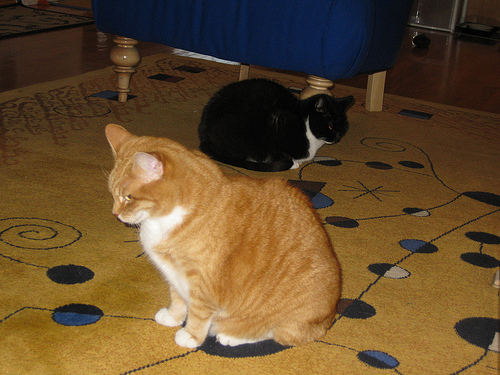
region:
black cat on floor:
[171, 68, 362, 192]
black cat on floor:
[197, 47, 355, 288]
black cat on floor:
[220, 42, 431, 153]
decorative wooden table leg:
[106, 33, 141, 103]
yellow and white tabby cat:
[96, 118, 353, 352]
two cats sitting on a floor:
[107, 62, 363, 356]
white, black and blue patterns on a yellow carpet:
[357, 128, 493, 348]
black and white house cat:
[194, 67, 358, 177]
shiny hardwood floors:
[418, 45, 495, 101]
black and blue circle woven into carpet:
[47, 296, 109, 331]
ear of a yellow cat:
[129, 146, 171, 188]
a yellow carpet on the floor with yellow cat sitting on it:
[15, 46, 224, 371]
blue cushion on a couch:
[152, 3, 409, 79]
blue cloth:
[278, 7, 420, 97]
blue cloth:
[170, 5, 392, 93]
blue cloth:
[228, 5, 442, 172]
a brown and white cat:
[84, 122, 346, 355]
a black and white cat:
[190, 71, 345, 175]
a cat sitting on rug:
[89, 115, 340, 352]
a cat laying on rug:
[184, 70, 352, 179]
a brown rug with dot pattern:
[11, 43, 494, 368]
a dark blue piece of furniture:
[94, 5, 409, 122]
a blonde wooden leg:
[106, 28, 144, 107]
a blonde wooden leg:
[299, 71, 326, 102]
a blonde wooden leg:
[364, 69, 389, 118]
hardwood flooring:
[394, 25, 494, 106]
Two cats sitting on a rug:
[73, 67, 377, 352]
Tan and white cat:
[94, 119, 350, 361]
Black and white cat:
[194, 73, 367, 175]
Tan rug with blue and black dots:
[0, 169, 110, 356]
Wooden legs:
[82, 36, 393, 114]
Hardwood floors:
[1, 29, 99, 93]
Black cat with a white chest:
[193, 71, 359, 171]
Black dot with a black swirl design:
[1, 204, 105, 294]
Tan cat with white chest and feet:
[96, 117, 348, 361]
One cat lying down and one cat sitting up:
[93, 75, 360, 354]